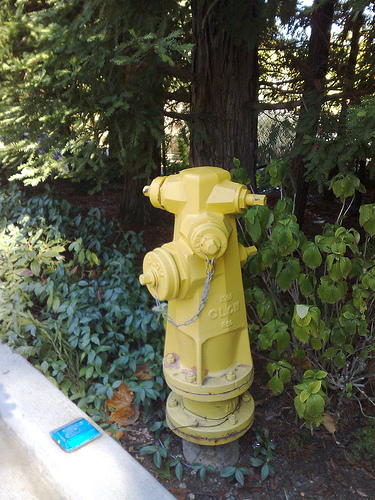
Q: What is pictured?
A: Fire hydrant.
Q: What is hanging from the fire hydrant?
A: Chain.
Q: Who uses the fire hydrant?
A: Firemen.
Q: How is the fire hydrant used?
A: To put out fires.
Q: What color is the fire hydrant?
A: Yellow.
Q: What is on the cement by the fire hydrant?
A: A blue reflector.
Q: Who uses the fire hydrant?
A: Fire fighters.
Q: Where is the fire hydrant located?
A: By the side of the road.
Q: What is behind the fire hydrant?
A: Trees.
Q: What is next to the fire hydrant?
A: Plants.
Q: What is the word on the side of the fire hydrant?
A: Glow.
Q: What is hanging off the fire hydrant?
A: A chain.